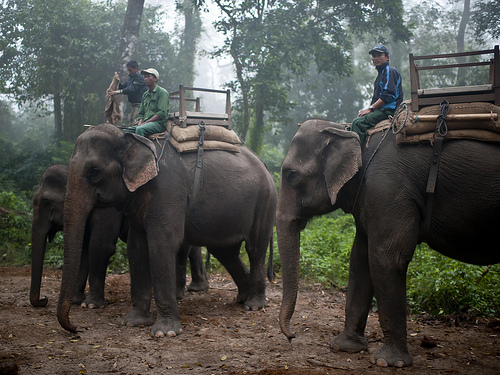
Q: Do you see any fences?
A: No, there are no fences.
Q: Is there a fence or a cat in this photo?
A: No, there are no fences or cats.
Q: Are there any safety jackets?
A: No, there are no safety jackets.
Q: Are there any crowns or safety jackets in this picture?
A: No, there are no safety jackets or crowns.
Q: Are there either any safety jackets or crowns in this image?
A: No, there are no safety jackets or crowns.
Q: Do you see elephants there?
A: Yes, there is an elephant.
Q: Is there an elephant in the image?
A: Yes, there is an elephant.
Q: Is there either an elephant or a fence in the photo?
A: Yes, there is an elephant.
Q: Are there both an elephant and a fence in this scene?
A: No, there is an elephant but no fences.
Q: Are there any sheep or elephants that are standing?
A: Yes, the elephant is standing.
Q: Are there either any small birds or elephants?
A: Yes, there is a small elephant.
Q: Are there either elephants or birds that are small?
A: Yes, the elephant is small.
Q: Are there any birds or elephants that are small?
A: Yes, the elephant is small.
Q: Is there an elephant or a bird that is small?
A: Yes, the elephant is small.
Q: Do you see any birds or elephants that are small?
A: Yes, the elephant is small.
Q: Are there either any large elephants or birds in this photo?
A: Yes, there is a large elephant.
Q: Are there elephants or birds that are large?
A: Yes, the elephant is large.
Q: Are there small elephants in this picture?
A: Yes, there is a small elephant.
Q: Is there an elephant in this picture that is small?
A: Yes, there is an elephant that is small.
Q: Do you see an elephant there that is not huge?
A: Yes, there is a small elephant.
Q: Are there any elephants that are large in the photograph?
A: Yes, there is a large elephant.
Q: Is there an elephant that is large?
A: Yes, there is an elephant that is large.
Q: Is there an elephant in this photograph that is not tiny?
A: Yes, there is a large elephant.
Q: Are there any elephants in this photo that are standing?
A: Yes, there is an elephant that is standing.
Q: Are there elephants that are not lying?
A: Yes, there is an elephant that is standing.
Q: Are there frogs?
A: No, there are no frogs.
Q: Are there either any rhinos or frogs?
A: No, there are no frogs or rhinos.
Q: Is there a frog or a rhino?
A: No, there are no frogs or rhinos.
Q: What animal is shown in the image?
A: The animal is an elephant.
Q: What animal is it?
A: The animal is an elephant.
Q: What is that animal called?
A: This is an elephant.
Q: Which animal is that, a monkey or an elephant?
A: This is an elephant.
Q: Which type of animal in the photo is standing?
A: The animal is an elephant.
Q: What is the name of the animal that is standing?
A: The animal is an elephant.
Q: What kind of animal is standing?
A: The animal is an elephant.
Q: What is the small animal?
A: The animal is an elephant.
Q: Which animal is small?
A: The animal is an elephant.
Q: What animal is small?
A: The animal is an elephant.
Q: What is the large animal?
A: The animal is an elephant.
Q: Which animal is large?
A: The animal is an elephant.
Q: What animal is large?
A: The animal is an elephant.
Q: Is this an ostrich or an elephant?
A: This is an elephant.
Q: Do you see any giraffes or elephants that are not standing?
A: No, there is an elephant but it is standing.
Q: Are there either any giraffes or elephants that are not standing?
A: No, there is an elephant but it is standing.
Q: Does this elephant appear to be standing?
A: Yes, the elephant is standing.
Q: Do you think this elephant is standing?
A: Yes, the elephant is standing.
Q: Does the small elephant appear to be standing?
A: Yes, the elephant is standing.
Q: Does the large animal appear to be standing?
A: Yes, the elephant is standing.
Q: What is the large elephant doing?
A: The elephant is standing.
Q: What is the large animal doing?
A: The elephant is standing.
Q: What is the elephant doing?
A: The elephant is standing.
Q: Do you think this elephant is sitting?
A: No, the elephant is standing.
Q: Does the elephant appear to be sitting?
A: No, the elephant is standing.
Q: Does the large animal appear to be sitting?
A: No, the elephant is standing.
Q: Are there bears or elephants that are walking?
A: No, there is an elephant but it is standing.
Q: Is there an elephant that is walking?
A: No, there is an elephant but it is standing.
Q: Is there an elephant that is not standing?
A: No, there is an elephant but it is standing.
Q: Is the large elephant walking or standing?
A: The elephant is standing.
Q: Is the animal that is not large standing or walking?
A: The elephant is standing.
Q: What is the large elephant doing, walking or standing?
A: The elephant is standing.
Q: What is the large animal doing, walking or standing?
A: The elephant is standing.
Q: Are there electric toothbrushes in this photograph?
A: No, there are no electric toothbrushes.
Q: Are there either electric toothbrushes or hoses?
A: No, there are no electric toothbrushes or hoses.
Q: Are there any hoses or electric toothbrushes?
A: No, there are no electric toothbrushes or hoses.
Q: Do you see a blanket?
A: Yes, there is a blanket.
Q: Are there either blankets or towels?
A: Yes, there is a blanket.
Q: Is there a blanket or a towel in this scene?
A: Yes, there is a blanket.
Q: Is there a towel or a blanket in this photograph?
A: Yes, there is a blanket.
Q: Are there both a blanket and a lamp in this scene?
A: No, there is a blanket but no lamps.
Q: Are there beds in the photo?
A: No, there are no beds.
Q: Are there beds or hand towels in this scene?
A: No, there are no beds or hand towels.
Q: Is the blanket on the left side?
A: Yes, the blanket is on the left of the image.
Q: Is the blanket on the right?
A: No, the blanket is on the left of the image.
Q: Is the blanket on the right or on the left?
A: The blanket is on the left of the image.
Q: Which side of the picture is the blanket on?
A: The blanket is on the left of the image.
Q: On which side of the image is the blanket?
A: The blanket is on the left of the image.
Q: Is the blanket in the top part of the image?
A: Yes, the blanket is in the top of the image.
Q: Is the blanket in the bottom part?
A: No, the blanket is in the top of the image.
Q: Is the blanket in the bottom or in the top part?
A: The blanket is in the top of the image.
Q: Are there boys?
A: No, there are no boys.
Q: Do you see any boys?
A: No, there are no boys.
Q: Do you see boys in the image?
A: No, there are no boys.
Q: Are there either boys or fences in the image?
A: No, there are no boys or fences.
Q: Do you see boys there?
A: No, there are no boys.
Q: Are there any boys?
A: No, there are no boys.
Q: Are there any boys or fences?
A: No, there are no boys or fences.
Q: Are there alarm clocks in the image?
A: No, there are no alarm clocks.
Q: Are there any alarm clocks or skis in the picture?
A: No, there are no alarm clocks or skis.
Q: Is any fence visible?
A: No, there are no fences.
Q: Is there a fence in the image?
A: No, there are no fences.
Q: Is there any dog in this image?
A: No, there are no dogs.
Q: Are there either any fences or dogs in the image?
A: No, there are no dogs or fences.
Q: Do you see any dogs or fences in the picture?
A: No, there are no dogs or fences.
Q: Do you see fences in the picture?
A: No, there are no fences.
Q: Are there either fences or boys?
A: No, there are no fences or boys.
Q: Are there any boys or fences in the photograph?
A: No, there are no fences or boys.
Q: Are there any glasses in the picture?
A: No, there are no glasses.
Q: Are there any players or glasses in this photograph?
A: No, there are no glasses or players.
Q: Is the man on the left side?
A: Yes, the man is on the left of the image.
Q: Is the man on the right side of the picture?
A: No, the man is on the left of the image.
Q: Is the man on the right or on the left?
A: The man is on the left of the image.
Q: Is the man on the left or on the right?
A: The man is on the left of the image.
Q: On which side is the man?
A: The man is on the left of the image.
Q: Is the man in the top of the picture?
A: Yes, the man is in the top of the image.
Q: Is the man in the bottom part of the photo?
A: No, the man is in the top of the image.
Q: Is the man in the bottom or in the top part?
A: The man is in the top of the image.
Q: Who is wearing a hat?
A: The man is wearing a hat.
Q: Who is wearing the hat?
A: The man is wearing a hat.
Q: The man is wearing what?
A: The man is wearing a hat.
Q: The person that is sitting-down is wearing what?
A: The man is wearing a hat.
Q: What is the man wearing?
A: The man is wearing a hat.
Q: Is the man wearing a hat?
A: Yes, the man is wearing a hat.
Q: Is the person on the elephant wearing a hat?
A: Yes, the man is wearing a hat.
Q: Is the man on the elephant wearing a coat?
A: No, the man is wearing a hat.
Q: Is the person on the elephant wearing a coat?
A: No, the man is wearing a hat.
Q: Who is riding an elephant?
A: The man is riding an elephant.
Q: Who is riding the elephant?
A: The man is riding an elephant.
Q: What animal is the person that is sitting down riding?
A: The man is riding an elephant.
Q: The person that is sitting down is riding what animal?
A: The man is riding an elephant.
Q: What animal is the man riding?
A: The man is riding an elephant.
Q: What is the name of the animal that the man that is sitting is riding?
A: The animal is an elephant.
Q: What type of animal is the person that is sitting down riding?
A: The man is riding an elephant.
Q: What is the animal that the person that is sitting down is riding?
A: The animal is an elephant.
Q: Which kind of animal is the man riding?
A: The man is riding an elephant.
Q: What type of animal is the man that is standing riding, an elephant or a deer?
A: The man is riding an elephant.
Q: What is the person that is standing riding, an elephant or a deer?
A: The man is riding an elephant.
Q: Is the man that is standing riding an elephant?
A: Yes, the man is riding an elephant.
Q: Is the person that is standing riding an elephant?
A: Yes, the man is riding an elephant.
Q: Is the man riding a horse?
A: No, the man is riding an elephant.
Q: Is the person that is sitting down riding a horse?
A: No, the man is riding an elephant.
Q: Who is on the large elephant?
A: The man is on the elephant.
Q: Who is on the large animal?
A: The man is on the elephant.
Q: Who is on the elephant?
A: The man is on the elephant.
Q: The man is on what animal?
A: The man is on the elephant.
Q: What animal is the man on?
A: The man is on the elephant.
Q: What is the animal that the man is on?
A: The animal is an elephant.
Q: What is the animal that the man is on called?
A: The animal is an elephant.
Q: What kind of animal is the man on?
A: The man is on the elephant.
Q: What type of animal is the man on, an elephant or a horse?
A: The man is on an elephant.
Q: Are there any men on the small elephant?
A: Yes, there is a man on the elephant.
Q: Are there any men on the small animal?
A: Yes, there is a man on the elephant.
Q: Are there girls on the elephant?
A: No, there is a man on the elephant.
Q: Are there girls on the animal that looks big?
A: No, there is a man on the elephant.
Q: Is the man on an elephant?
A: Yes, the man is on an elephant.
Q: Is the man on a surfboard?
A: No, the man is on an elephant.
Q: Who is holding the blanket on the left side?
A: The man is holding the blanket.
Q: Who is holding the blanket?
A: The man is holding the blanket.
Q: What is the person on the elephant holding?
A: The man is holding the blanket.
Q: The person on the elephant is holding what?
A: The man is holding the blanket.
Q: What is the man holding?
A: The man is holding the blanket.